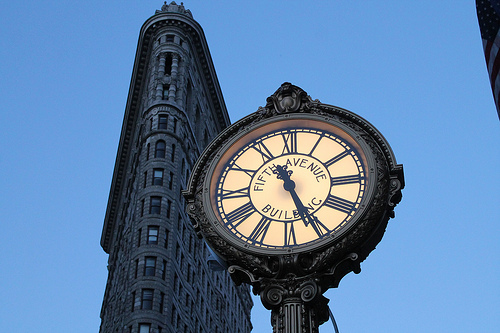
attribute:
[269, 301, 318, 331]
post — black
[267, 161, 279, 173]
h — black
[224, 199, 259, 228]
numerals — roman numerals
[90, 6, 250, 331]
building — curved, large, grey, gray, triangle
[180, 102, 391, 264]
hour hand — black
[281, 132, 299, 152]
xii — black